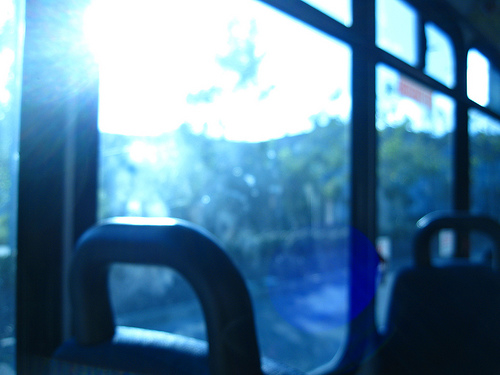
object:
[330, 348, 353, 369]
grommet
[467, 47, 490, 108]
window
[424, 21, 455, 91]
window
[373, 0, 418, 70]
window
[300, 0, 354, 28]
window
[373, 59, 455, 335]
window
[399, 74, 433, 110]
sticker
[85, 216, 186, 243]
top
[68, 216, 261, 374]
headrest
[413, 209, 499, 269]
headrest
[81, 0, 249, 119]
sun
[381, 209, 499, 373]
bus seat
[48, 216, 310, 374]
bus seat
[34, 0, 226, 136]
sun ray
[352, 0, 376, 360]
metal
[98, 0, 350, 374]
window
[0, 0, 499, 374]
bus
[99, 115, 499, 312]
shrubs